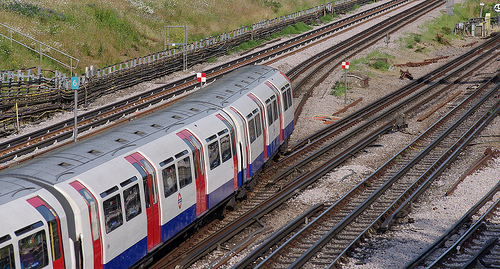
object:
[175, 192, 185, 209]
logo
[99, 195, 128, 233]
windows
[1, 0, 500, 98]
grass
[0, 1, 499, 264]
tracks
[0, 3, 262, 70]
grassy area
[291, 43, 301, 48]
metal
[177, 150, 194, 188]
window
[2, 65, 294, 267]
train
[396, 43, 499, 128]
tracks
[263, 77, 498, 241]
tracks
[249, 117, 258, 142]
square window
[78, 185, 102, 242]
window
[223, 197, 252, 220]
stripe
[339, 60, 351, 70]
sign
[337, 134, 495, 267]
gravel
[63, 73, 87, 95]
sign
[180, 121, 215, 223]
red door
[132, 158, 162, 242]
door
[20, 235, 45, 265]
window